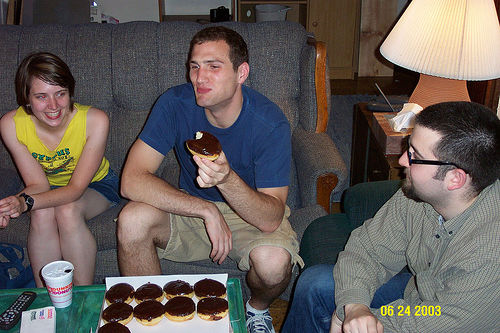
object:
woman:
[1, 48, 121, 290]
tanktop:
[15, 103, 114, 187]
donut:
[134, 281, 164, 302]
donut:
[163, 279, 196, 300]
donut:
[96, 323, 134, 333]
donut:
[103, 283, 135, 306]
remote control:
[0, 288, 38, 331]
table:
[0, 274, 253, 331]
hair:
[468, 113, 499, 172]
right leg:
[113, 199, 200, 274]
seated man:
[278, 98, 500, 333]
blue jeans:
[279, 263, 417, 332]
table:
[344, 93, 401, 185]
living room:
[1, 1, 498, 333]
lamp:
[374, 0, 499, 131]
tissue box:
[368, 108, 414, 161]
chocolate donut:
[194, 278, 226, 298]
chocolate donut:
[197, 295, 229, 321]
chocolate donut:
[163, 296, 197, 322]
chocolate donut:
[134, 300, 165, 326]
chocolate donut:
[102, 300, 132, 324]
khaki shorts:
[155, 199, 303, 272]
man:
[280, 101, 499, 331]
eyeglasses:
[402, 134, 467, 171]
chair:
[300, 178, 404, 266]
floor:
[334, 76, 377, 92]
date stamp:
[377, 304, 396, 316]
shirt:
[334, 178, 499, 333]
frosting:
[200, 295, 220, 299]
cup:
[42, 260, 74, 308]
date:
[377, 302, 442, 318]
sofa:
[0, 18, 348, 289]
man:
[114, 23, 308, 333]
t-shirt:
[136, 83, 291, 203]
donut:
[181, 129, 223, 160]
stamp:
[412, 305, 444, 317]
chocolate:
[107, 287, 128, 299]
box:
[95, 271, 232, 333]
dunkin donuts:
[41, 260, 71, 282]